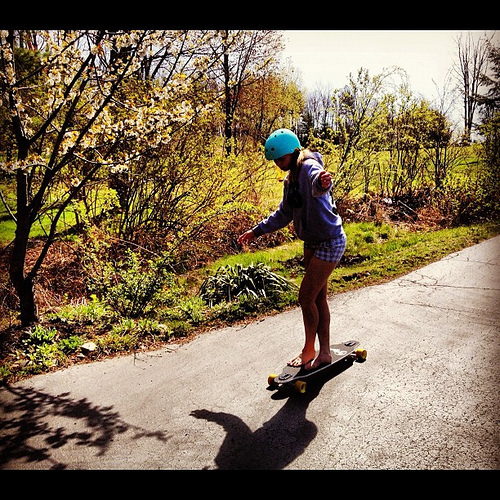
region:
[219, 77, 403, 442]
a girl skateboarding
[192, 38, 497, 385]
a girl skateboarding outside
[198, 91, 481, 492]
a girl skateboarding on sidewalk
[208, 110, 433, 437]
a girl skateboarding barefoot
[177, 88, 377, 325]
a girl wearing a helmet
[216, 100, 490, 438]
a girl wearing a blue helmet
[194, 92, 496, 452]
a girl wearing shorts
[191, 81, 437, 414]
a girl wearing a hoodie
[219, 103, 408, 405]
a young girl skateboarding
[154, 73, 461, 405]
a young girl with helmet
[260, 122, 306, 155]
A light blue bike helmet.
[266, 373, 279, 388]
The yellow wheel of the skateboard.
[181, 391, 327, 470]
The skateboarder's shadow.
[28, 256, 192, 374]
An outcropping of brush.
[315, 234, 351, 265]
Checkered bike short shorts.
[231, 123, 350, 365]
A girl riding a skateboard.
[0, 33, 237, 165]
A small tree with white blossoms.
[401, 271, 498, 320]
Cracks in the pavement.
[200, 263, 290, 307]
A large green plant with long leaves.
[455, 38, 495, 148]
A tall, dead tree.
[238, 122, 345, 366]
the girl on the skateboard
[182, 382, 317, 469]
the girl's shadow on the ground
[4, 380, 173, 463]
the tree's shadow on the ground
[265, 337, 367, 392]
the skateboard on the ground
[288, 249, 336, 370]
the girl's two legs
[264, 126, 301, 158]
the girl's blue helmet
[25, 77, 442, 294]
the greenery next to the pavement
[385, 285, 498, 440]
the dark gray pavement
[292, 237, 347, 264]
the girl's shorts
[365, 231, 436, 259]
the grass near the pavement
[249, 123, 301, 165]
Girl wearing a helment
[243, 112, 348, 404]
Girl riding a skateboard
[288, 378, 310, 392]
Skateboard with yellow wheels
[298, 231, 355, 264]
Girl wearing plaid shorts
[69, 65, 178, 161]
White flower buds on a tree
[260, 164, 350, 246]
Girl wearing a blue hoodie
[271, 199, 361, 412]
Girl riding a black skate board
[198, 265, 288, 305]
Crab Grass in a field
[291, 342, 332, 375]
Girl riding a skateboard without shoes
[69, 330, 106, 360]
Rock in a field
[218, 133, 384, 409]
Girl is riding skateboard.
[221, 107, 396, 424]
The girl is barefoot.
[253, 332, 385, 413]
The skateboard has wheels.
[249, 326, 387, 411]
The wheels are yellow.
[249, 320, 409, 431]
The wheels are round.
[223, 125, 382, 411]
Girl wearing a helmet.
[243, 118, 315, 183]
The helmet is blue.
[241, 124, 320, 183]
The helmet has holes in it.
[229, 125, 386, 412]
Girl is wearing shorts.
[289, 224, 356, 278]
The shorts are checked.